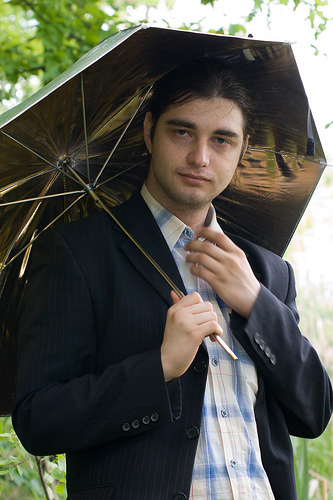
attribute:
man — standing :
[112, 60, 265, 268]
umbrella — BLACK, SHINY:
[0, 25, 328, 235]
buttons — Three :
[207, 353, 221, 374]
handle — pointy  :
[211, 333, 238, 365]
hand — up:
[183, 228, 257, 315]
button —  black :
[185, 423, 200, 447]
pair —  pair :
[162, 114, 250, 146]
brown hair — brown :
[150, 62, 256, 157]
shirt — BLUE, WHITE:
[26, 192, 323, 495]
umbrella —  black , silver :
[35, 25, 310, 127]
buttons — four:
[118, 409, 164, 430]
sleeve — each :
[14, 345, 158, 470]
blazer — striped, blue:
[1, 186, 332, 499]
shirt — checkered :
[141, 182, 279, 498]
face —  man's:
[153, 91, 249, 205]